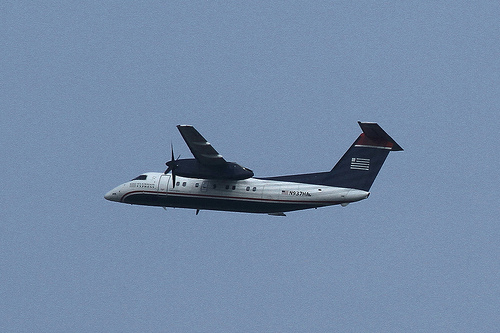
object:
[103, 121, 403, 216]
plane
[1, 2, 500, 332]
sky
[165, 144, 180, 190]
propeller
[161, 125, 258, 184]
wing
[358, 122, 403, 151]
rutter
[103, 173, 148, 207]
cockpit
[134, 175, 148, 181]
front window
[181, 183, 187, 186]
window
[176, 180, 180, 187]
window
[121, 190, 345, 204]
stripe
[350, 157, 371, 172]
flag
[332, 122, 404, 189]
tail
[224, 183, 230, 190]
window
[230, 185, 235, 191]
window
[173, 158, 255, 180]
engine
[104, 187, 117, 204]
nose